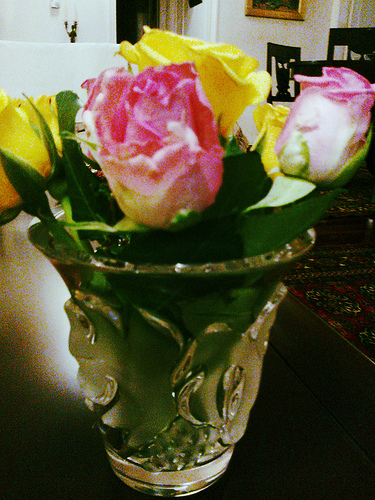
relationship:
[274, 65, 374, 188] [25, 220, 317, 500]
flower in flower pot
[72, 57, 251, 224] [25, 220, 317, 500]
flower in flower pot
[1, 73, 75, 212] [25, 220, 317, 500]
flower in flower pot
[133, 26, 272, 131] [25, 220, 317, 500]
flower in flower pot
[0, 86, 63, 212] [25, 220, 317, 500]
flower in flower pot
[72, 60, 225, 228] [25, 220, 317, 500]
flower in flower pot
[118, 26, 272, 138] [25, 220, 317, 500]
flower in flower pot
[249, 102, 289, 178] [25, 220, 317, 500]
flowers in flower pot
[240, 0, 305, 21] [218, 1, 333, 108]
picture on wall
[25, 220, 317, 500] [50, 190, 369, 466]
flower pot on table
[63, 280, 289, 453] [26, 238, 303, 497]
images on vase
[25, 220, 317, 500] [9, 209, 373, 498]
flower pot on table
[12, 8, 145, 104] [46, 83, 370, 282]
wall behind table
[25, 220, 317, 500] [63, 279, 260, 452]
flower pot has design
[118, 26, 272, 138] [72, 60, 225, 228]
flower beyond flower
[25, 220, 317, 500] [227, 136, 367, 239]
flower pot has leaves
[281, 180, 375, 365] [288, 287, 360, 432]
carpet on ground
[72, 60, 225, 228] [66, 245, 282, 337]
flower in vase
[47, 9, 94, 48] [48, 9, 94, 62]
candles in candle holder